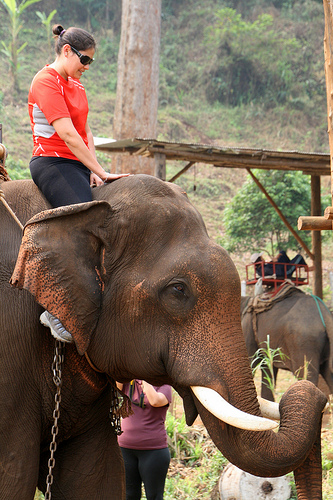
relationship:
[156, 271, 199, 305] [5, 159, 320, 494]
eye of elephant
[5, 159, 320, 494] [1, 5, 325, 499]
elephant in picture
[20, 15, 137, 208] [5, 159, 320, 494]
woman on top elephant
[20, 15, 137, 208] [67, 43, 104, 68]
woman wearing sun glasses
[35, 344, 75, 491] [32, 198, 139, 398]
chain around elephant's neck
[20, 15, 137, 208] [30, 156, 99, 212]
woman wearing black pants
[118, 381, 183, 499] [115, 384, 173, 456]
woman wearing purple shirt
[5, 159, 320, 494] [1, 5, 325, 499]
elephant at zoo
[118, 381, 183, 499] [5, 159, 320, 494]
woman behind elephant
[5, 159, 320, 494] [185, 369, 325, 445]
elephant has two tusks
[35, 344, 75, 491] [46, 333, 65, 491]
chain has chain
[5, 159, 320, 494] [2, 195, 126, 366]
elephant has brown ear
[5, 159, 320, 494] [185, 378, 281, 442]
elephant has tusk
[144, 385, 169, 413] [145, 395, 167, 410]
elbow seen a part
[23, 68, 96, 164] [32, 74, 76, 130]
top has sleeve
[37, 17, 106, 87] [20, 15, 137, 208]
hair of lady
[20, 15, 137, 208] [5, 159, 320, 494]
woman riding an elephant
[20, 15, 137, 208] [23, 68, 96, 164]
woman in red shirt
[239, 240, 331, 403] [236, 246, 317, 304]
elephant with saddle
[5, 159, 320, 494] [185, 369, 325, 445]
elephant with tusks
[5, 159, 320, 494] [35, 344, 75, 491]
elephant wearing chain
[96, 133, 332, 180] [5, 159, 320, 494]
platform behind elephant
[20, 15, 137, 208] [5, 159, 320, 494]
person preparing elephant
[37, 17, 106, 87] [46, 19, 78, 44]
hair in a bun